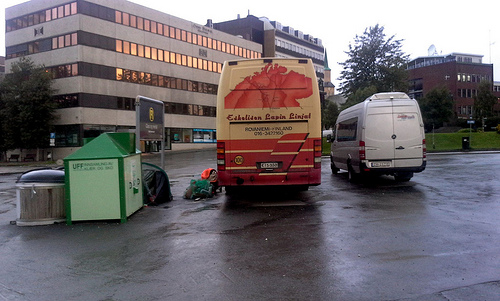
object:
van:
[331, 88, 427, 176]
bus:
[213, 56, 321, 201]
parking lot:
[211, 150, 498, 300]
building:
[0, 1, 264, 148]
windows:
[110, 37, 128, 53]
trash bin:
[64, 132, 148, 221]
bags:
[184, 170, 217, 201]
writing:
[225, 112, 308, 134]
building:
[392, 50, 495, 133]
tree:
[4, 60, 58, 156]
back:
[219, 56, 316, 183]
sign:
[139, 103, 162, 138]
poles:
[133, 97, 170, 171]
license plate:
[262, 162, 280, 171]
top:
[70, 132, 140, 157]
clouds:
[397, 0, 492, 43]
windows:
[333, 116, 357, 144]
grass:
[442, 124, 488, 147]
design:
[225, 68, 309, 110]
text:
[243, 125, 296, 137]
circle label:
[234, 152, 247, 164]